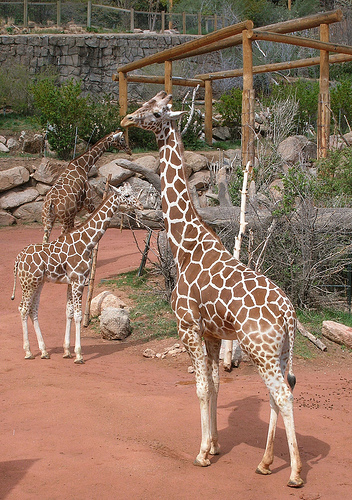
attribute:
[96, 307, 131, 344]
stones — small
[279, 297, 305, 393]
tail — white, black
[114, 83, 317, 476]
giraffe — tallest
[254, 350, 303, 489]
legs — back legs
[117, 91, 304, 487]
giraffe — brown, tall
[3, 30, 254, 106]
wall — large, gray, rock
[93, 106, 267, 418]
giraffe — prominent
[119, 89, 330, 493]
giraffe — prominent